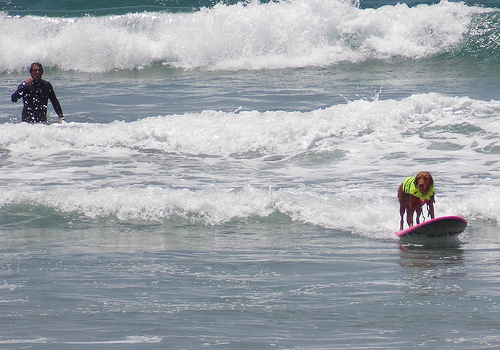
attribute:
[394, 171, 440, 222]
dog — wet, brown, surfing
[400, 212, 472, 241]
surfboard — pink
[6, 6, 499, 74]
wave — big, white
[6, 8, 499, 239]
ocean — here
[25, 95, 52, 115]
wetsuit — dark, black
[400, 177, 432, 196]
vest — green